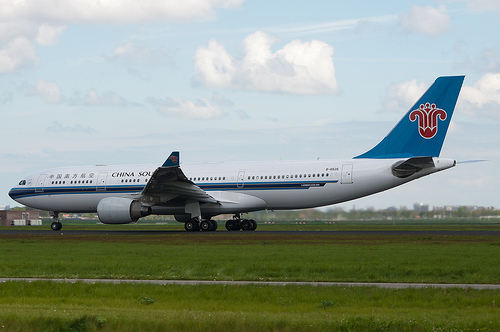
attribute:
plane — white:
[5, 74, 472, 226]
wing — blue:
[139, 153, 215, 222]